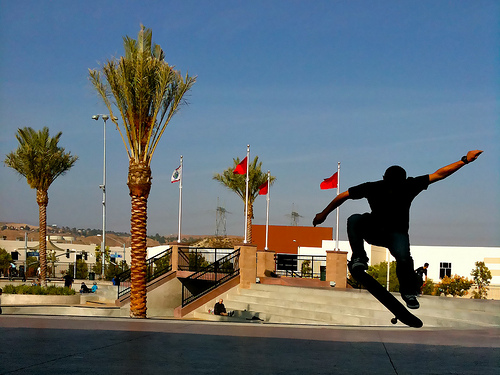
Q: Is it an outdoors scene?
A: Yes, it is outdoors.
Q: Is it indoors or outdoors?
A: It is outdoors.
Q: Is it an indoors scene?
A: No, it is outdoors.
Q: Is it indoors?
A: No, it is outdoors.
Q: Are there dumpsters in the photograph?
A: No, there are no dumpsters.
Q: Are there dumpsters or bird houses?
A: No, there are no dumpsters or bird houses.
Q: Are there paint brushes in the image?
A: No, there are no paint brushes.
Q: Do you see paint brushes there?
A: No, there are no paint brushes.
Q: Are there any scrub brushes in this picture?
A: No, there are no scrub brushes.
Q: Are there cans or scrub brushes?
A: No, there are no scrub brushes or cans.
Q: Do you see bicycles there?
A: No, there are no bicycles.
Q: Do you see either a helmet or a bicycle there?
A: No, there are no bicycles or helmets.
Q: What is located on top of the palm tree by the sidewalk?
A: The leaves are on top of the palm.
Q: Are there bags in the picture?
A: No, there are no bags.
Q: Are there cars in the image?
A: No, there are no cars.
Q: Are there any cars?
A: No, there are no cars.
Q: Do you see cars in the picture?
A: No, there are no cars.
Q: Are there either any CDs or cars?
A: No, there are no cars or cds.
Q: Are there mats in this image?
A: No, there are no mats.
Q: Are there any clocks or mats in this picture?
A: No, there are no mats or clocks.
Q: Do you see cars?
A: No, there are no cars.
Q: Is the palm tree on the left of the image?
A: Yes, the palm tree is on the left of the image.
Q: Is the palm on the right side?
A: No, the palm is on the left of the image.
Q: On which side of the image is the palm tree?
A: The palm tree is on the left of the image.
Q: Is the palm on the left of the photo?
A: Yes, the palm is on the left of the image.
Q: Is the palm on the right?
A: No, the palm is on the left of the image.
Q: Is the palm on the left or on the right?
A: The palm is on the left of the image.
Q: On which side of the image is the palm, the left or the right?
A: The palm is on the left of the image.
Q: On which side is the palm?
A: The palm is on the left of the image.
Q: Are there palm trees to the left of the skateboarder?
A: Yes, there is a palm tree to the left of the skateboarder.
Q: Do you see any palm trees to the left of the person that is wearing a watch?
A: Yes, there is a palm tree to the left of the skateboarder.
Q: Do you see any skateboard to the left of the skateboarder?
A: No, there is a palm tree to the left of the skateboarder.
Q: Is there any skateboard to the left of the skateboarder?
A: No, there is a palm tree to the left of the skateboarder.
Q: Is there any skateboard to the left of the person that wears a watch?
A: No, there is a palm tree to the left of the skateboarder.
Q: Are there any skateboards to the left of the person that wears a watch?
A: No, there is a palm tree to the left of the skateboarder.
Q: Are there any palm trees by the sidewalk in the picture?
A: Yes, there is a palm tree by the sidewalk.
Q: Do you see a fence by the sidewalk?
A: No, there is a palm tree by the sidewalk.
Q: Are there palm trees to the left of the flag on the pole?
A: Yes, there is a palm tree to the left of the flag.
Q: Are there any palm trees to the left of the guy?
A: Yes, there is a palm tree to the left of the guy.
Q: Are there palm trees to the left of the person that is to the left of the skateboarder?
A: Yes, there is a palm tree to the left of the guy.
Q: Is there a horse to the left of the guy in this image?
A: No, there is a palm tree to the left of the guy.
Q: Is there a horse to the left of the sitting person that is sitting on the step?
A: No, there is a palm tree to the left of the guy.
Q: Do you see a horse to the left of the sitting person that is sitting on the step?
A: No, there is a palm tree to the left of the guy.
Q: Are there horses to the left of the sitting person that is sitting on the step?
A: No, there is a palm tree to the left of the guy.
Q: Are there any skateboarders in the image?
A: Yes, there is a skateboarder.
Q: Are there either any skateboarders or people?
A: Yes, there is a skateboarder.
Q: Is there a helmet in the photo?
A: No, there are no helmets.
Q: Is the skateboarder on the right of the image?
A: Yes, the skateboarder is on the right of the image.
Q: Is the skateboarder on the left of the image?
A: No, the skateboarder is on the right of the image.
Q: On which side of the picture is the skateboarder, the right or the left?
A: The skateboarder is on the right of the image.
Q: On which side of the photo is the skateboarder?
A: The skateboarder is on the right of the image.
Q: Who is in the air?
A: The skateboarder is in the air.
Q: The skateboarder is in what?
A: The skateboarder is in the air.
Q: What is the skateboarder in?
A: The skateboarder is in the air.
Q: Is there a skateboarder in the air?
A: Yes, there is a skateboarder in the air.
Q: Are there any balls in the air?
A: No, there is a skateboarder in the air.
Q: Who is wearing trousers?
A: The skateboarder is wearing trousers.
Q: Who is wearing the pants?
A: The skateboarder is wearing trousers.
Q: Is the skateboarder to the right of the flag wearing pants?
A: Yes, the skateboarder is wearing pants.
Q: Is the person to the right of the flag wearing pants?
A: Yes, the skateboarder is wearing pants.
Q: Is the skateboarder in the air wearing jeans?
A: No, the skateboarder is wearing pants.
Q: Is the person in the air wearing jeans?
A: No, the skateboarder is wearing pants.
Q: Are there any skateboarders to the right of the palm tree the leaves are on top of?
A: Yes, there is a skateboarder to the right of the palm tree.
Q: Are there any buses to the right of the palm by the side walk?
A: No, there is a skateboarder to the right of the palm.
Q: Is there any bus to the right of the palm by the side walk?
A: No, there is a skateboarder to the right of the palm.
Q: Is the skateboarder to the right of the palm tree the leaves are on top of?
A: Yes, the skateboarder is to the right of the palm tree.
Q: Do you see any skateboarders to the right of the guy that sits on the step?
A: Yes, there is a skateboarder to the right of the guy.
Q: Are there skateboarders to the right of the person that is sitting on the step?
A: Yes, there is a skateboarder to the right of the guy.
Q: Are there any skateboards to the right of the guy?
A: No, there is a skateboarder to the right of the guy.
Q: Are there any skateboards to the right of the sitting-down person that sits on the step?
A: No, there is a skateboarder to the right of the guy.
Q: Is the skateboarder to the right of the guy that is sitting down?
A: Yes, the skateboarder is to the right of the guy.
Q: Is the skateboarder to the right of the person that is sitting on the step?
A: Yes, the skateboarder is to the right of the guy.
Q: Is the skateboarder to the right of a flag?
A: Yes, the skateboarder is to the right of a flag.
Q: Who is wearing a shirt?
A: The skateboarder is wearing a shirt.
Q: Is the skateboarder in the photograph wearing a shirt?
A: Yes, the skateboarder is wearing a shirt.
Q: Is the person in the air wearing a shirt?
A: Yes, the skateboarder is wearing a shirt.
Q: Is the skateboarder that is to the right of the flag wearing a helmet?
A: No, the skateboarder is wearing a shirt.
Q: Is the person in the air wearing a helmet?
A: No, the skateboarder is wearing a shirt.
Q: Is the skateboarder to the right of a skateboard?
A: No, the skateboarder is to the right of the flag.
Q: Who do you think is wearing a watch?
A: The skateboarder is wearing a watch.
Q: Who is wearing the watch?
A: The skateboarder is wearing a watch.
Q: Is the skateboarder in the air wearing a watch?
A: Yes, the skateboarder is wearing a watch.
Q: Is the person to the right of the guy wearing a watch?
A: Yes, the skateboarder is wearing a watch.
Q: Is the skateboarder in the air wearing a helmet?
A: No, the skateboarder is wearing a watch.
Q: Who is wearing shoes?
A: The skateboarder is wearing shoes.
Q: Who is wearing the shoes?
A: The skateboarder is wearing shoes.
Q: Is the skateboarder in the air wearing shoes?
A: Yes, the skateboarder is wearing shoes.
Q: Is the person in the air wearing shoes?
A: Yes, the skateboarder is wearing shoes.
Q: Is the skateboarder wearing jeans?
A: No, the skateboarder is wearing shoes.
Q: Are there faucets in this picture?
A: No, there are no faucets.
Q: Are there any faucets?
A: No, there are no faucets.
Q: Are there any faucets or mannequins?
A: No, there are no faucets or mannequins.